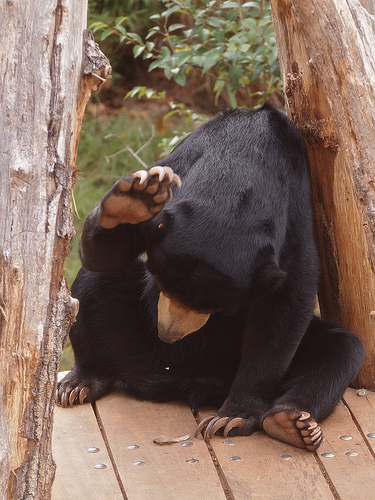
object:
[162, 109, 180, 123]
leaf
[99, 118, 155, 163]
branch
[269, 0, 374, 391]
trunk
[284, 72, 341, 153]
bark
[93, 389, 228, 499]
board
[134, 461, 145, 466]
bolt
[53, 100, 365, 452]
bear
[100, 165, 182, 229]
paw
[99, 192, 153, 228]
pad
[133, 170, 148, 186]
claw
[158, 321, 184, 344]
nose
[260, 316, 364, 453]
leg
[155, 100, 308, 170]
back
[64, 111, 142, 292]
grass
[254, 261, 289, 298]
ear